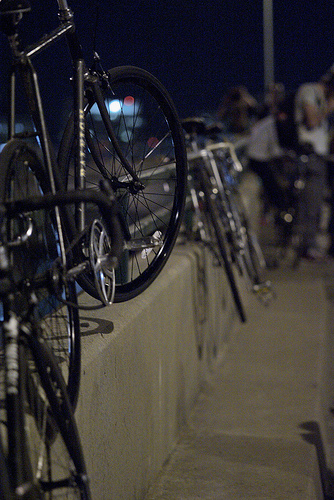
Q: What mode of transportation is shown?
A: Bicycles.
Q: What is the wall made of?
A: Concrete.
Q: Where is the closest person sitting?
A: Concrete wall.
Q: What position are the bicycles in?
A: Hanging.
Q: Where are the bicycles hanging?
A: On the railing.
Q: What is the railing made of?
A: Metal.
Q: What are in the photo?
A: Bicycle.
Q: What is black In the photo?
A: Front tire on the black bike.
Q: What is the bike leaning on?
A: A cement wall.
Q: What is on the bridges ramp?
A: A bicycle.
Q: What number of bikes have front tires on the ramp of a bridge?
A: Two bikes.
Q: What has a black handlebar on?
A: A bike.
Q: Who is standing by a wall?
A: Group of people.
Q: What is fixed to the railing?
A: A bike.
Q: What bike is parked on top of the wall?
A: Black bike.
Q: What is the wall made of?
A: Cement.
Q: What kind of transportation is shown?
A: Bicycles.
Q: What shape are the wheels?
A: Round.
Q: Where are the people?
A: In the background of the bikes.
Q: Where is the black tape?
A: Around the handlebars.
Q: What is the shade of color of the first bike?
A: Black.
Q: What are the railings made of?
A: Steel.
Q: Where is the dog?
A: There is no dog?.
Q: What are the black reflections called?
A: Shadows.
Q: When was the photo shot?
A: During the night.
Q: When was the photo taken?
A: Night.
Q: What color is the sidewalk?
A: Grey.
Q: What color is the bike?
A: Black.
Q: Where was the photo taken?
A: Sidewalk.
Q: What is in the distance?
A: Lights.